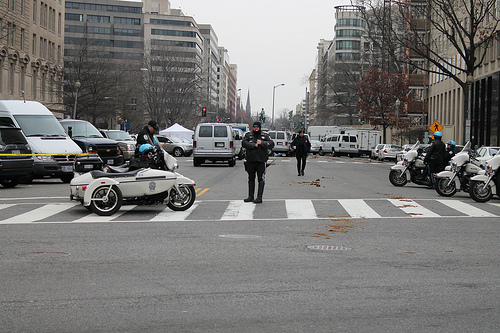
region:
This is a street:
[87, 69, 352, 294]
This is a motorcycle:
[107, 172, 149, 216]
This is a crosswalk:
[169, 154, 386, 249]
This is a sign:
[375, 112, 498, 177]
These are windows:
[194, 129, 238, 153]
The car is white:
[205, 111, 249, 185]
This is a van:
[192, 126, 260, 177]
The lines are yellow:
[198, 166, 218, 206]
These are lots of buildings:
[110, 8, 210, 98]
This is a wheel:
[82, 155, 149, 232]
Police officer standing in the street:
[236, 113, 273, 201]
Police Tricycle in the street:
[81, 140, 197, 213]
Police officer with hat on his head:
[246, 118, 268, 135]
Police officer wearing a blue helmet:
[431, 125, 442, 140]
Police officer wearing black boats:
[234, 158, 266, 210]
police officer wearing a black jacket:
[289, 135, 315, 154]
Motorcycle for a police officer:
[383, 145, 441, 180]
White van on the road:
[318, 132, 364, 158]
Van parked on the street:
[186, 110, 243, 175]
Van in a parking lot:
[13, 96, 83, 170]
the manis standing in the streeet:
[238, 119, 275, 209]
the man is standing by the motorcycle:
[134, 115, 168, 160]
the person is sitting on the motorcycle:
[422, 128, 446, 173]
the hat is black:
[145, 117, 162, 134]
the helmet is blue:
[431, 130, 442, 141]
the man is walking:
[288, 125, 312, 179]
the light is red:
[199, 105, 209, 113]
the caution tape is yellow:
[35, 149, 67, 160]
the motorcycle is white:
[118, 175, 155, 192]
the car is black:
[86, 138, 109, 154]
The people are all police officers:
[25, 111, 486, 271]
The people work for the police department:
[5, 90, 485, 245]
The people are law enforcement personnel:
[0, 90, 492, 246]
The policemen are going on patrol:
[5, 101, 495, 231]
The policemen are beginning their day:
[0, 105, 495, 225]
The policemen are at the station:
[0, 112, 496, 262]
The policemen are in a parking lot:
[2, 105, 493, 217]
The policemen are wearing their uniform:
[11, 105, 496, 252]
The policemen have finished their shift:
[1, 113, 496, 229]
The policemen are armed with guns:
[5, 111, 498, 214]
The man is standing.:
[228, 116, 280, 211]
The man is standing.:
[281, 118, 327, 185]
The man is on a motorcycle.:
[383, 123, 470, 203]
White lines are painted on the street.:
[0, 143, 499, 331]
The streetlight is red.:
[195, 103, 217, 120]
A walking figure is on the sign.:
[421, 110, 452, 140]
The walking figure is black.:
[423, 115, 453, 142]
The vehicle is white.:
[316, 128, 362, 160]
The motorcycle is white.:
[378, 124, 468, 194]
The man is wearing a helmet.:
[388, 125, 469, 201]